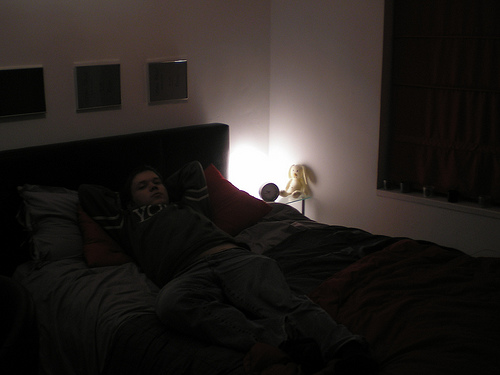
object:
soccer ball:
[130, 164, 170, 206]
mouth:
[151, 191, 164, 198]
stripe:
[183, 194, 220, 202]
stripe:
[184, 179, 211, 193]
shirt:
[77, 161, 253, 287]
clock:
[259, 183, 280, 204]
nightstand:
[238, 178, 312, 216]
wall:
[0, 0, 270, 197]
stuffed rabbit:
[278, 163, 309, 199]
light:
[230, 138, 304, 193]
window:
[378, 0, 499, 212]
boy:
[77, 160, 384, 373]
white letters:
[132, 201, 183, 222]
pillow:
[18, 184, 81, 262]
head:
[125, 167, 170, 206]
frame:
[153, 59, 190, 102]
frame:
[75, 60, 123, 109]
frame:
[0, 65, 44, 115]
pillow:
[74, 160, 275, 269]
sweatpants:
[155, 246, 364, 362]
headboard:
[0, 122, 230, 245]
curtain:
[380, 3, 500, 202]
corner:
[225, 0, 321, 200]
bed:
[0, 121, 498, 372]